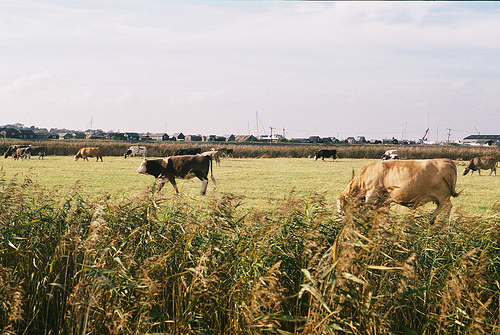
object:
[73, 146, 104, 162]
cow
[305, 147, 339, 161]
cow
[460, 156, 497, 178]
cow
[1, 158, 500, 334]
field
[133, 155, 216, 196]
cow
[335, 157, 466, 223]
cow